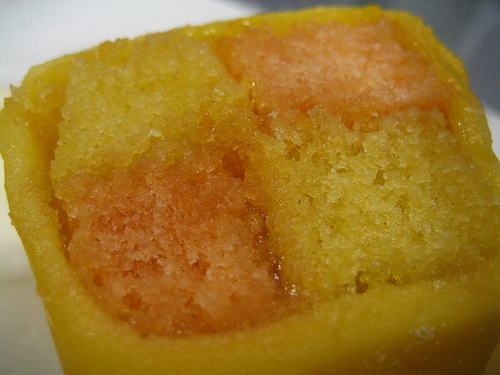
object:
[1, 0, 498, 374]
table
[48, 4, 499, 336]
orange squares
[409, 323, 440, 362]
white substance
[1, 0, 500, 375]
cake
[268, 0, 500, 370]
section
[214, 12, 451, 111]
part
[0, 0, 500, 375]
plate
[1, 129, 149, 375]
border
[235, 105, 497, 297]
edible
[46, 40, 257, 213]
cake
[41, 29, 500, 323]
sheep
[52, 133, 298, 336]
cake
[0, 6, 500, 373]
yellow food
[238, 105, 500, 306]
part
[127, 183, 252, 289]
spot